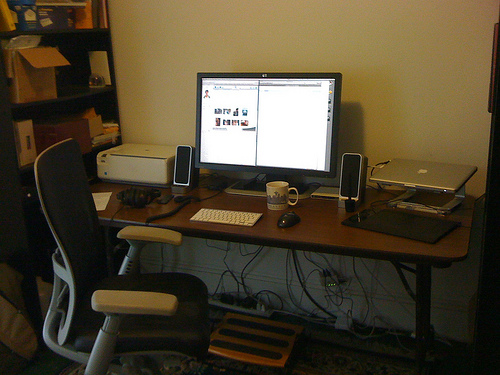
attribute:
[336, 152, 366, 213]
speaker — tall, black, gray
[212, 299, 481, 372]
rug — floor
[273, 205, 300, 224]
mouse — black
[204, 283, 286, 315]
power strip — overloaded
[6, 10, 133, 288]
shelf — crowded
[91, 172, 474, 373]
table — brown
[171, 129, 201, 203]
speaker — computer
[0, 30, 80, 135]
box — open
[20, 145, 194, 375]
chair — black, gray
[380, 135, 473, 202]
computer — gray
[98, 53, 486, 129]
wall — painted, white 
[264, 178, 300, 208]
mug — white , coffee mug